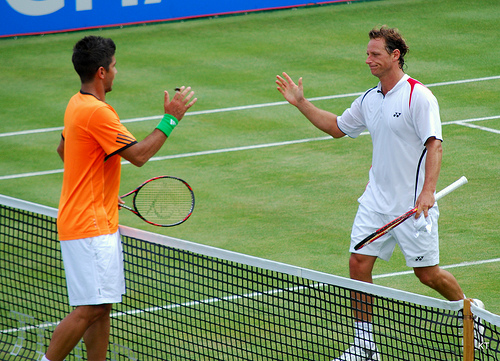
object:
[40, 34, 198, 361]
man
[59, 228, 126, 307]
white shorts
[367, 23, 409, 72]
blonde hair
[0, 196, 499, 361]
net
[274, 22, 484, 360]
man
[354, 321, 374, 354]
sock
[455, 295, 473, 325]
sock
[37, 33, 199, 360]
player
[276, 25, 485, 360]
player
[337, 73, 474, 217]
shirt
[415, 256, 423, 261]
logo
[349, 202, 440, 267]
shorts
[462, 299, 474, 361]
pole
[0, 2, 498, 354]
court